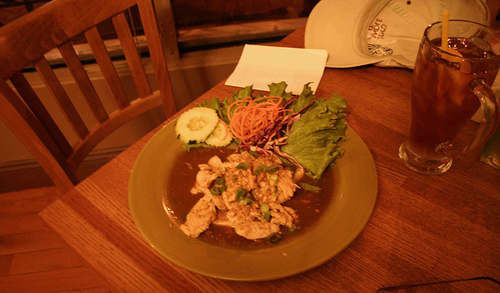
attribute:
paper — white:
[228, 34, 332, 98]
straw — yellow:
[436, 10, 452, 68]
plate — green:
[278, 240, 332, 284]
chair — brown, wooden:
[3, 5, 143, 131]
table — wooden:
[341, 72, 398, 131]